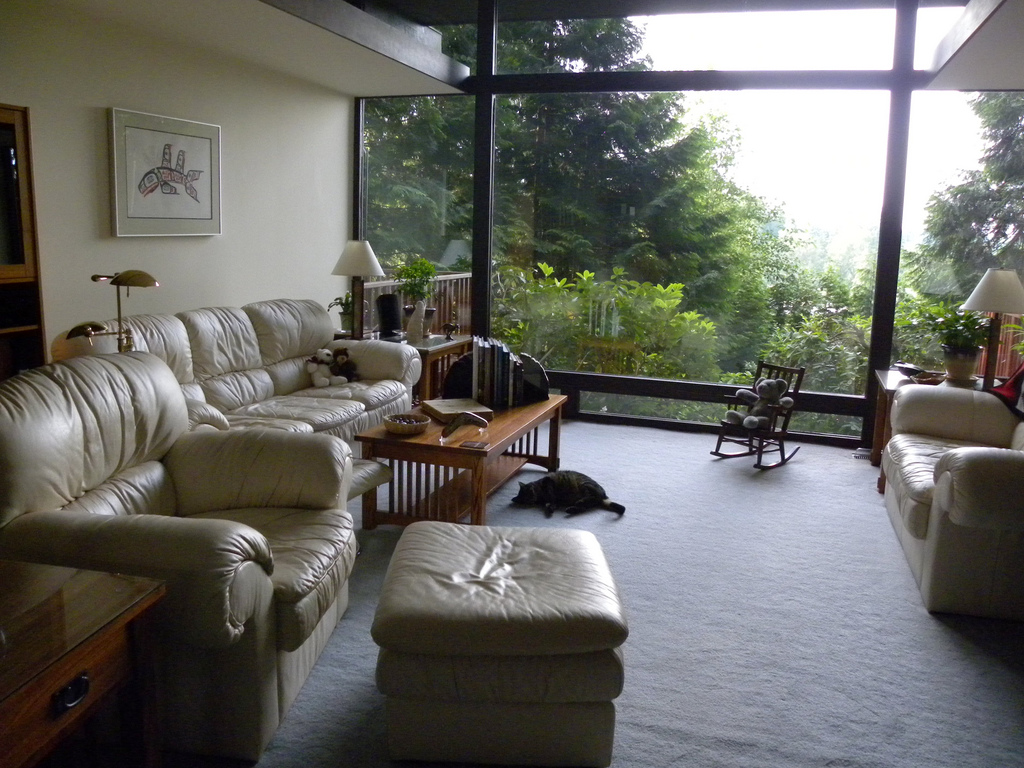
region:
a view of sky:
[675, 119, 862, 234]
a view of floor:
[720, 525, 823, 655]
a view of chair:
[340, 538, 705, 729]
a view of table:
[242, 319, 638, 490]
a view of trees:
[616, 220, 719, 319]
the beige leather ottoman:
[364, 485, 660, 764]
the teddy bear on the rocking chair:
[724, 373, 791, 427]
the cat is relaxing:
[504, 462, 628, 520]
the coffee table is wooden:
[355, 386, 564, 526]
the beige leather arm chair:
[1, 348, 359, 761]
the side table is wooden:
[0, 551, 178, 758]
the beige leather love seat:
[863, 370, 1016, 615]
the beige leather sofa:
[46, 294, 433, 495]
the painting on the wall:
[98, 90, 225, 243]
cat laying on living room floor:
[510, 467, 631, 522]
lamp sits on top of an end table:
[957, 265, 1021, 390]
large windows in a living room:
[352, 19, 1021, 444]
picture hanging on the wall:
[103, 101, 225, 241]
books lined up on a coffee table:
[466, 332, 550, 410]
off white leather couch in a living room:
[47, 291, 421, 484]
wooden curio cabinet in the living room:
[0, 100, 52, 379]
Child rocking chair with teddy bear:
[705, 354, 810, 481]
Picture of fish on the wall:
[93, 95, 227, 252]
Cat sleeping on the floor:
[504, 464, 632, 529]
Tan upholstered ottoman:
[361, 509, 628, 765]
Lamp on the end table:
[330, 233, 385, 338]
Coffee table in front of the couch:
[352, 382, 569, 531]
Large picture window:
[485, 86, 898, 410]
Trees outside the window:
[351, 3, 1022, 440]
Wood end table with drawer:
[0, 554, 182, 766]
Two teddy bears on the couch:
[296, 335, 363, 399]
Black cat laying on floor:
[511, 467, 628, 525]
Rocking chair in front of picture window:
[707, 358, 807, 473]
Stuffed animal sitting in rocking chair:
[724, 370, 795, 432]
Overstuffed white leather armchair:
[3, 348, 359, 763]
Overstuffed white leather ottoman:
[370, 518, 630, 766]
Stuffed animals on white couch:
[303, 345, 357, 390]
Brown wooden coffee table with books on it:
[354, 391, 570, 529]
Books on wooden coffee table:
[419, 334, 533, 423]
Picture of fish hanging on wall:
[107, 102, 225, 239]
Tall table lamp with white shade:
[332, 239, 389, 345]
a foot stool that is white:
[387, 494, 578, 725]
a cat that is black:
[523, 458, 613, 526]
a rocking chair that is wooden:
[709, 350, 805, 483]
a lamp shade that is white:
[956, 261, 1021, 315]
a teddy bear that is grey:
[718, 385, 792, 433]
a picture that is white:
[105, 91, 238, 244]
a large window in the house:
[375, 32, 1023, 429]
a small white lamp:
[331, 240, 379, 324]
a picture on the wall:
[114, 108, 228, 235]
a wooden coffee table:
[379, 369, 569, 519]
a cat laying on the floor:
[515, 468, 630, 526]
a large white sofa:
[79, 303, 430, 446]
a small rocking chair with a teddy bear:
[721, 367, 797, 473]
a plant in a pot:
[938, 312, 978, 382]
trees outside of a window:
[385, 26, 746, 396]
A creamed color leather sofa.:
[88, 273, 427, 502]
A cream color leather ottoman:
[365, 519, 635, 753]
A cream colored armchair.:
[17, 351, 403, 763]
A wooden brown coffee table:
[368, 354, 584, 541]